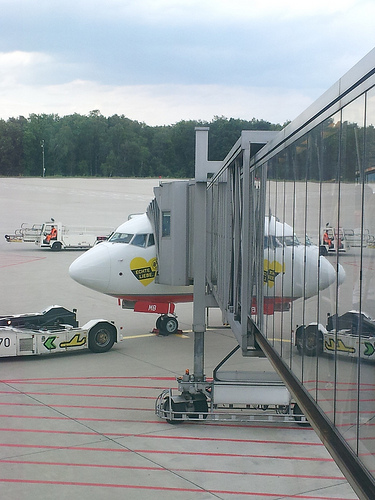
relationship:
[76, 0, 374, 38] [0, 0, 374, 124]
white cloud in blue sky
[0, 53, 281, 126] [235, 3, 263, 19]
clouds in sky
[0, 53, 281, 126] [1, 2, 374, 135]
clouds in sky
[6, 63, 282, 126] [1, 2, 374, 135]
clouds in sky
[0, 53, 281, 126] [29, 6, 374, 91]
clouds in sky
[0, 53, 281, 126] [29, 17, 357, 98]
clouds in sky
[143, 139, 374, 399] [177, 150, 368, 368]
bridge of plane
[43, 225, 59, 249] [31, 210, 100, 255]
man driving truck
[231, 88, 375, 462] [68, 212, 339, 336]
line of airplane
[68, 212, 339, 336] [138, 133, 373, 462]
airplane on bridge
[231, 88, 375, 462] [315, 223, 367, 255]
line of car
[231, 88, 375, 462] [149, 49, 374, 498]
line on bridge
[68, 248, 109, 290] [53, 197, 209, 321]
nose of plane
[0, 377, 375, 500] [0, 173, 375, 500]
line on ground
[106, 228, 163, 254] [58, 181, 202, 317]
windows on plane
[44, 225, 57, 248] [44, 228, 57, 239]
man wearing orange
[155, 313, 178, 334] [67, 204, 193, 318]
wheel under airplane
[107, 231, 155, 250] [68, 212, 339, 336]
windows of airplane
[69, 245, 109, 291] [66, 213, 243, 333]
nose of plane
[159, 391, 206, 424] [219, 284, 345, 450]
front wheels of bridge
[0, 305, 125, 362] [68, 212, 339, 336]
car near airplane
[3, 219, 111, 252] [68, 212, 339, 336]
truck near airplane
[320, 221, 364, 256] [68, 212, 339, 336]
car near airplane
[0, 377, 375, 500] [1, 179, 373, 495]
line on ground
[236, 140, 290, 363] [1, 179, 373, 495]
line on ground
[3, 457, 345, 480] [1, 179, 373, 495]
line on ground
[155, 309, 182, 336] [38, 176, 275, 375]
wheel on airplane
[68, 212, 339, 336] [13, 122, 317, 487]
airplane at airport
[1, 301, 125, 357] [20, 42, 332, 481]
car at airport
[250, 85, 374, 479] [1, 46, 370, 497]
windows of airport